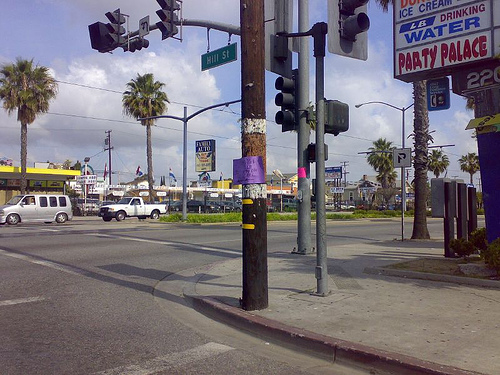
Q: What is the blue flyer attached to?
A: Utility pole.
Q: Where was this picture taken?
A: Intersection.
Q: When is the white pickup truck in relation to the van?
A: Behind it.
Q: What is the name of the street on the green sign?
A: Mill St.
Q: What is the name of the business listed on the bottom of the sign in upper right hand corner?
A: PARTY PLACE.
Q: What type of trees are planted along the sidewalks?
A: Palm trees.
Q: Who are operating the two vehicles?
A: Their respective drivers.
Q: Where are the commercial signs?
A: Along the street.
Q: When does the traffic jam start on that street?
A: During rush hours.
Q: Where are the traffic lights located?
A: On the side street and hanging on top of the street.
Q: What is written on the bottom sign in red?
A: Party Palace.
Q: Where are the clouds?
A: The sky.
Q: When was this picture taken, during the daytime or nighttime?
A: Daytime.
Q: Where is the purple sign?
A: Telephone pole.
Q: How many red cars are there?
A: Zero.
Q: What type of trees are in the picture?
A: Palm.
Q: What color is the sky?
A: Blue.